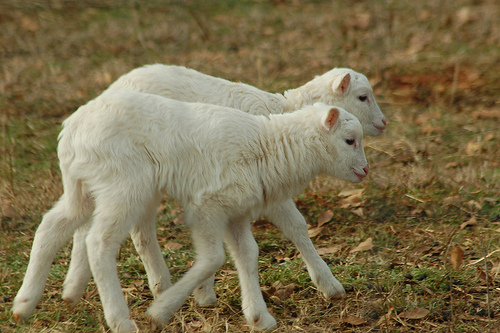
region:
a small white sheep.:
[10, 96, 388, 331]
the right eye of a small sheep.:
[335, 129, 371, 156]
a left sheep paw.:
[233, 278, 289, 329]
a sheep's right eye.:
[320, 128, 365, 163]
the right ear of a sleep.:
[316, 98, 346, 140]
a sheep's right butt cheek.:
[75, 134, 158, 328]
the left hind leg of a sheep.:
[6, 163, 91, 331]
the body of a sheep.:
[115, 83, 295, 190]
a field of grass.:
[0, 3, 497, 331]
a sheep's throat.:
[248, 114, 313, 192]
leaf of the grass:
[341, 218, 382, 270]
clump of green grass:
[380, 257, 458, 304]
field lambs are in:
[407, 140, 472, 278]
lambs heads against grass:
[303, 66, 392, 214]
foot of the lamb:
[278, 245, 363, 317]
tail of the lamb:
[54, 118, 86, 231]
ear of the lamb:
[296, 100, 353, 159]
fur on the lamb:
[255, 137, 305, 173]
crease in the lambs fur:
[248, 173, 274, 213]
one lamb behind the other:
[223, 66, 371, 164]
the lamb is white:
[35, 48, 378, 323]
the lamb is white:
[71, 119, 267, 312]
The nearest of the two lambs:
[7, 88, 373, 331]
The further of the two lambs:
[61, 61, 389, 309]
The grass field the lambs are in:
[1, 1, 498, 331]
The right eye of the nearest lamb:
[339, 129, 358, 149]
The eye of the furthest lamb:
[354, 89, 371, 106]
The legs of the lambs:
[9, 180, 362, 331]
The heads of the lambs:
[290, 56, 393, 193]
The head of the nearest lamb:
[309, 101, 371, 185]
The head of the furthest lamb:
[316, 64, 392, 139]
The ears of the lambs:
[319, 70, 353, 133]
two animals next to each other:
[26, 60, 413, 262]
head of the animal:
[288, 97, 373, 195]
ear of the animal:
[329, 65, 359, 92]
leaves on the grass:
[323, 201, 405, 268]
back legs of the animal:
[11, 236, 151, 326]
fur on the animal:
[147, 113, 219, 172]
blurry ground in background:
[208, 16, 278, 57]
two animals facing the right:
[131, 51, 419, 315]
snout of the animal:
[351, 151, 379, 191]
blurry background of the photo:
[6, 11, 71, 81]